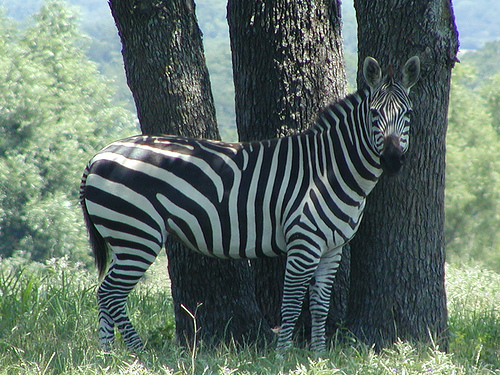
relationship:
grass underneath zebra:
[2, 275, 499, 374] [70, 53, 431, 362]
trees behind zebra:
[3, 1, 500, 287] [70, 53, 431, 362]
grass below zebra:
[2, 275, 499, 374] [70, 53, 431, 362]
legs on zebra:
[78, 236, 349, 354] [70, 53, 431, 362]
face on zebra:
[372, 86, 414, 180] [70, 53, 431, 362]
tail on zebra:
[68, 162, 122, 282] [70, 53, 431, 362]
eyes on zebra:
[364, 104, 414, 123] [70, 53, 431, 362]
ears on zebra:
[357, 51, 423, 90] [70, 53, 431, 362]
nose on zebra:
[373, 142, 409, 177] [70, 53, 431, 362]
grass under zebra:
[2, 275, 499, 374] [70, 53, 431, 362]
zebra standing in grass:
[70, 53, 431, 362] [2, 275, 499, 374]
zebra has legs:
[70, 53, 431, 362] [78, 236, 349, 354]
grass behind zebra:
[2, 275, 499, 374] [70, 53, 431, 362]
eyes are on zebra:
[364, 104, 414, 123] [70, 53, 431, 362]